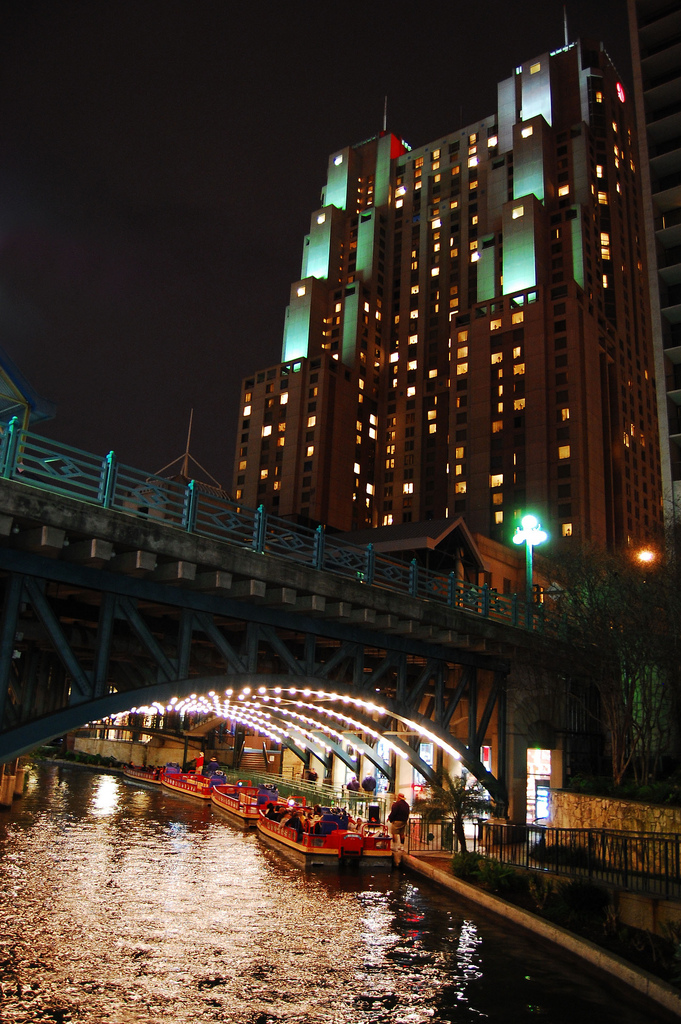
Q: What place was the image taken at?
A: It was taken at the river.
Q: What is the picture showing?
A: It is showing a river.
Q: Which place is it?
A: It is a river.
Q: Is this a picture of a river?
A: Yes, it is showing a river.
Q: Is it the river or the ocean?
A: It is the river.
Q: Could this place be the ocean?
A: No, it is the river.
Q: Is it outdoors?
A: Yes, it is outdoors.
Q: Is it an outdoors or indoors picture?
A: It is outdoors.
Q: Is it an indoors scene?
A: No, it is outdoors.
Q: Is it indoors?
A: No, it is outdoors.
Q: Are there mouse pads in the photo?
A: No, there are no mouse pads.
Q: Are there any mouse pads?
A: No, there are no mouse pads.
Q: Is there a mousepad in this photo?
A: No, there are no mouse pads.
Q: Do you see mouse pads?
A: No, there are no mouse pads.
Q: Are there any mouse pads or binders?
A: No, there are no mouse pads or binders.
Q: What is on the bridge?
A: The gate is on the bridge.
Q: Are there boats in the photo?
A: Yes, there is a boat.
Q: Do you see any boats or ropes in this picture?
A: Yes, there is a boat.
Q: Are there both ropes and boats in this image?
A: No, there is a boat but no ropes.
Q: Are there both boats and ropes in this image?
A: No, there is a boat but no ropes.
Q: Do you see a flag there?
A: No, there are no flags.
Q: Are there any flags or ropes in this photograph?
A: No, there are no flags or ropes.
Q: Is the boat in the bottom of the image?
A: Yes, the boat is in the bottom of the image.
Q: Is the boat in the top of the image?
A: No, the boat is in the bottom of the image.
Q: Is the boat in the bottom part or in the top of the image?
A: The boat is in the bottom of the image.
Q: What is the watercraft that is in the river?
A: The watercraft is a boat.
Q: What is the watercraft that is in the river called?
A: The watercraft is a boat.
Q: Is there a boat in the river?
A: Yes, there is a boat in the river.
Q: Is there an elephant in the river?
A: No, there is a boat in the river.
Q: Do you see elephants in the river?
A: No, there is a boat in the river.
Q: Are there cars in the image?
A: No, there are no cars.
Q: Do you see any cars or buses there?
A: No, there are no cars or buses.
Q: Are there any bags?
A: No, there are no bags.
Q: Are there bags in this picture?
A: No, there are no bags.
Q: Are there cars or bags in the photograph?
A: No, there are no bags or cars.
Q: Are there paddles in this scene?
A: No, there are no paddles.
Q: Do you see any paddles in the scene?
A: No, there are no paddles.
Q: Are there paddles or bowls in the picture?
A: No, there are no paddles or bowls.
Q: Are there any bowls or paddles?
A: No, there are no paddles or bowls.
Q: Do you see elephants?
A: No, there are no elephants.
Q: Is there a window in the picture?
A: Yes, there is a window.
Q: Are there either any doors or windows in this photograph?
A: Yes, there is a window.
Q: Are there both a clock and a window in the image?
A: No, there is a window but no clocks.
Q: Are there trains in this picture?
A: No, there are no trains.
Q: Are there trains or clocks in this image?
A: No, there are no trains or clocks.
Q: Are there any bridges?
A: Yes, there is a bridge.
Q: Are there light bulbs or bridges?
A: Yes, there is a bridge.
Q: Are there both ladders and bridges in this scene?
A: No, there is a bridge but no ladders.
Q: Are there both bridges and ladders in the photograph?
A: No, there is a bridge but no ladders.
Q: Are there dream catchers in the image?
A: No, there are no dream catchers.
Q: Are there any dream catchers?
A: No, there are no dream catchers.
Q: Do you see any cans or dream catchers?
A: No, there are no dream catchers or cans.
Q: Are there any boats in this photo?
A: Yes, there is a boat.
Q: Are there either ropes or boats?
A: Yes, there is a boat.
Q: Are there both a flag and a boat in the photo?
A: No, there is a boat but no flags.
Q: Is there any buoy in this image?
A: No, there are no buoys.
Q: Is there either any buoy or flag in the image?
A: No, there are no buoys or flags.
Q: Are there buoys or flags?
A: No, there are no buoys or flags.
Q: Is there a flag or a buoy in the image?
A: No, there are no buoys or flags.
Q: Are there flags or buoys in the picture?
A: No, there are no buoys or flags.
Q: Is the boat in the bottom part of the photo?
A: Yes, the boat is in the bottom of the image.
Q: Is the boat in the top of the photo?
A: No, the boat is in the bottom of the image.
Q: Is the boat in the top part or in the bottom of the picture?
A: The boat is in the bottom of the image.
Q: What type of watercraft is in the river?
A: The watercraft is a boat.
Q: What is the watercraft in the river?
A: The watercraft is a boat.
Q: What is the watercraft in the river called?
A: The watercraft is a boat.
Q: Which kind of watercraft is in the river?
A: The watercraft is a boat.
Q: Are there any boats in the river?
A: Yes, there is a boat in the river.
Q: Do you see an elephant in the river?
A: No, there is a boat in the river.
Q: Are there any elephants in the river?
A: No, there is a boat in the river.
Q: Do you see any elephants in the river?
A: No, there is a boat in the river.